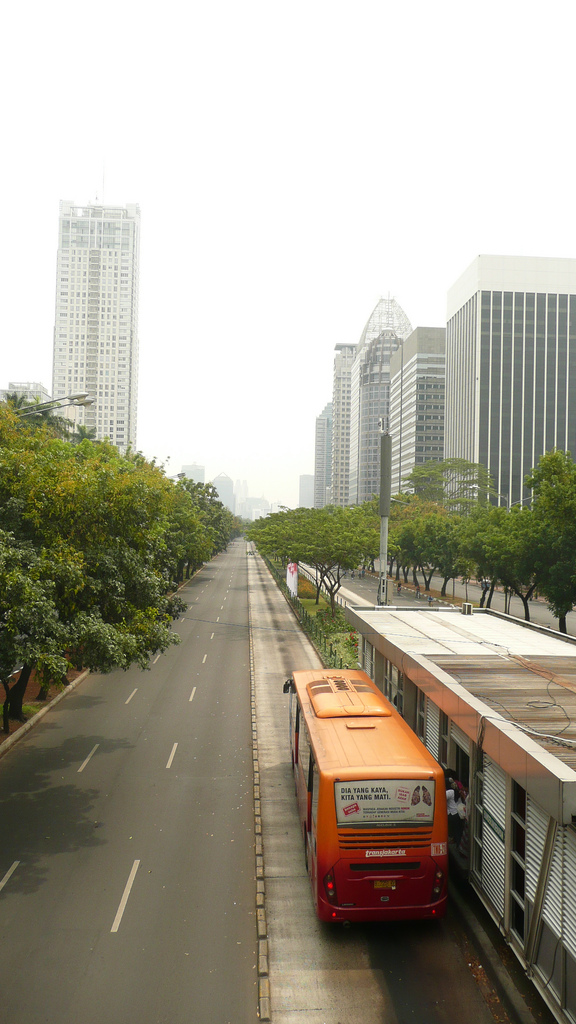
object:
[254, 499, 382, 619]
trees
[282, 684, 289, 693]
mirror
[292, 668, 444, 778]
roof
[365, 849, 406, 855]
writing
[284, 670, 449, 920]
bus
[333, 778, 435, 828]
ad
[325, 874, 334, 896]
tail light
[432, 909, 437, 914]
tail light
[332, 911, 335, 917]
tail light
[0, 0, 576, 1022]
area